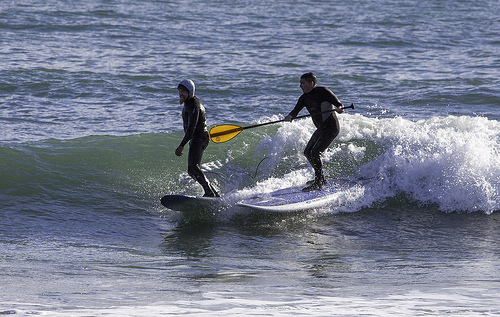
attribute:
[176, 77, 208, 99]
helmet — blue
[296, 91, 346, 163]
watersuit — black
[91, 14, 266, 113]
ocean — green, blue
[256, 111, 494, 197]
wave — present, here, small, crested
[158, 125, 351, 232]
board — blue, white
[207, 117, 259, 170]
paddle — orange, held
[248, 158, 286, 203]
cord — spiraled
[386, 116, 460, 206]
water — foamy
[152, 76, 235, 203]
surfer — here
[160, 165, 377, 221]
surfboard — blue, white, ridden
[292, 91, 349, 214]
wetsuit — grey, black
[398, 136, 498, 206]
foam — here, white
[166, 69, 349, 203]
people — surfing